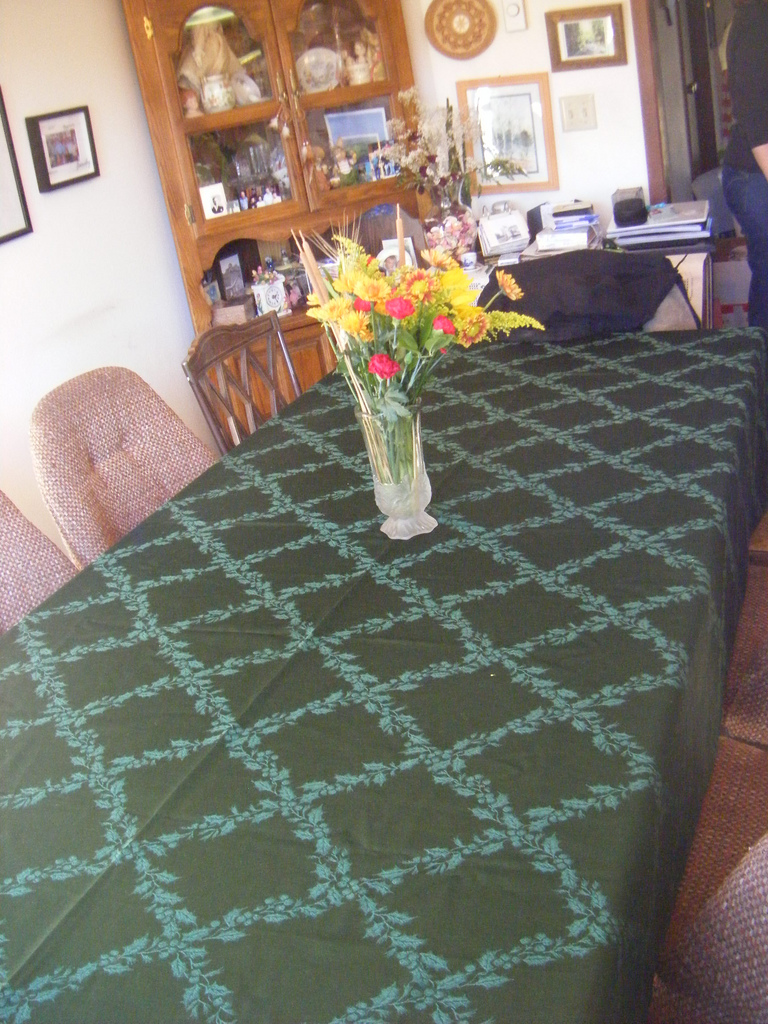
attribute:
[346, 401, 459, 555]
vase — clear, glass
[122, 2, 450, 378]
cabinet — brown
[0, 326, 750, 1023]
cloth — dark green, long, wide, green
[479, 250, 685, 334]
coat — black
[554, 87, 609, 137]
switches — white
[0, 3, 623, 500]
wall — white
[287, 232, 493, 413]
flowers — yellow, fresh, red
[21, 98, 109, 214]
picture — white, hanging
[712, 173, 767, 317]
jeans — blue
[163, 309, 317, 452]
chair — brown